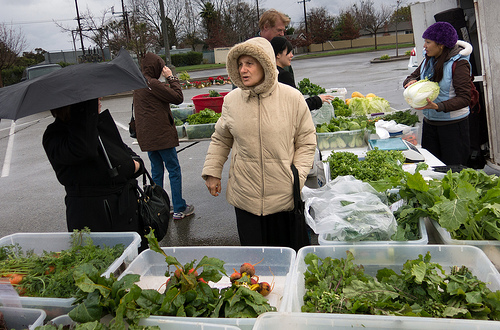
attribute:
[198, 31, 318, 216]
coat — brown, tan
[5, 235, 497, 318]
stand — outdoor, vegetable stand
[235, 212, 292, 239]
pants — black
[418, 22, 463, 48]
cap — purple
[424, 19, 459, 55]
hat — purple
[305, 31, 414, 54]
fence — wooden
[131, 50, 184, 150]
coat — brown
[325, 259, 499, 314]
leaves — green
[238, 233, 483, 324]
bin — plastic, clear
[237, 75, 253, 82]
mouth — open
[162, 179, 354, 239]
jeans — blue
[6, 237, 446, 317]
bins — full, plastic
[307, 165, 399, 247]
bags — clear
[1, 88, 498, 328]
fruits — various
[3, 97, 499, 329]
vegetables — various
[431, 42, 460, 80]
hair — dark